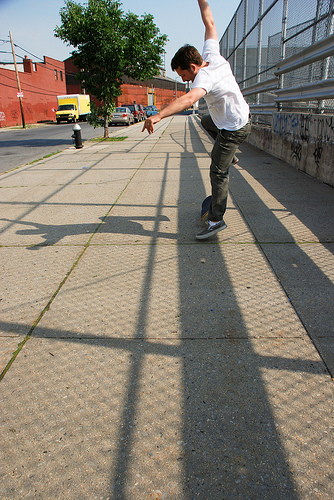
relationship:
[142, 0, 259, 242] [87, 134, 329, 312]
man on sidewalk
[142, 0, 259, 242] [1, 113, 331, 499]
man skateboards on sidewalk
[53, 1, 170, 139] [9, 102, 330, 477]
tree on sidewalk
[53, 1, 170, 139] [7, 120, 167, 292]
tree on sidewalk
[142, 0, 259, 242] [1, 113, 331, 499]
man on sidewalk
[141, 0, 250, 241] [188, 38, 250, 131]
white shirt on man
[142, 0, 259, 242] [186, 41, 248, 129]
man wears shirt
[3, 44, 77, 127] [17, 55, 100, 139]
building has walls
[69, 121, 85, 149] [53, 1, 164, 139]
fire hydrant next to tree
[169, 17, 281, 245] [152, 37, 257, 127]
boy has on t-shirt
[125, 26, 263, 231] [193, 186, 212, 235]
skater on skateboard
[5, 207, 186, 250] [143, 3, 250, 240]
shadow of skateboarder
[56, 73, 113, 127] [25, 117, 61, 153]
truck on street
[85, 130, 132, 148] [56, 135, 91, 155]
grass along curb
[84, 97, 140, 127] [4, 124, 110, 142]
cars on side of street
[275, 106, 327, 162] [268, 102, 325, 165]
graffiti on wall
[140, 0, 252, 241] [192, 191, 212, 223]
skater on skateboard